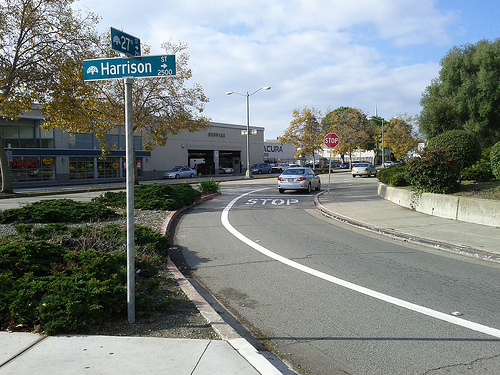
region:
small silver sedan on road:
[266, 157, 326, 203]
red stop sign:
[315, 130, 345, 190]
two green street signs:
[70, 15, 172, 370]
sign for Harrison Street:
[70, 45, 175, 80]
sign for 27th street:
[102, 18, 152, 54]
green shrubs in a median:
[3, 170, 225, 336]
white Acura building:
[260, 135, 300, 160]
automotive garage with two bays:
[175, 135, 250, 175]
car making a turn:
[247, 141, 329, 202]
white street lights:
[218, 75, 278, 183]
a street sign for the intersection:
[75, 20, 185, 330]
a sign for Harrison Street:
[81, 54, 178, 83]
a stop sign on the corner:
[321, 130, 342, 192]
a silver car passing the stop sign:
[276, 163, 323, 197]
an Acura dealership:
[263, 138, 326, 167]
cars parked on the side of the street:
[159, 161, 290, 177]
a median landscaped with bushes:
[0, 175, 222, 333]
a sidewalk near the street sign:
[0, 333, 305, 374]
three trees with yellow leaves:
[278, 104, 422, 171]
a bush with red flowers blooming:
[405, 148, 462, 197]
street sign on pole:
[76, 23, 202, 320]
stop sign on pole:
[318, 125, 349, 180]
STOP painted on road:
[239, 192, 305, 214]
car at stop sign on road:
[272, 120, 340, 205]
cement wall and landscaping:
[385, 112, 496, 222]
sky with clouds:
[311, 13, 452, 76]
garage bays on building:
[176, 117, 274, 185]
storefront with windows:
[3, 119, 135, 190]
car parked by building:
[158, 153, 201, 180]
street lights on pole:
[220, 71, 279, 186]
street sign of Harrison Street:
[83, 54, 178, 86]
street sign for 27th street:
[102, 19, 145, 56]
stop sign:
[320, 128, 340, 145]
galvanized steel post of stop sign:
[321, 146, 331, 186]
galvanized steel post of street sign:
[115, 80, 142, 324]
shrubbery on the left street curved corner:
[10, 176, 221, 331]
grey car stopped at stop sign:
[277, 160, 319, 195]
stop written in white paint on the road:
[244, 188, 301, 218]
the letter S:
[243, 196, 257, 210]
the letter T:
[257, 196, 272, 210]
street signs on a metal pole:
[83, 30, 178, 332]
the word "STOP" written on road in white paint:
[247, 190, 297, 207]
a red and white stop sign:
[323, 130, 338, 146]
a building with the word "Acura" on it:
[262, 143, 294, 172]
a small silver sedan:
[281, 166, 323, 193]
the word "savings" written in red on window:
[8, 155, 45, 171]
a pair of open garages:
[182, 145, 241, 177]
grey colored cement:
[2, 190, 262, 373]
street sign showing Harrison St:
[82, 55, 174, 79]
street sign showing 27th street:
[109, 26, 142, 58]